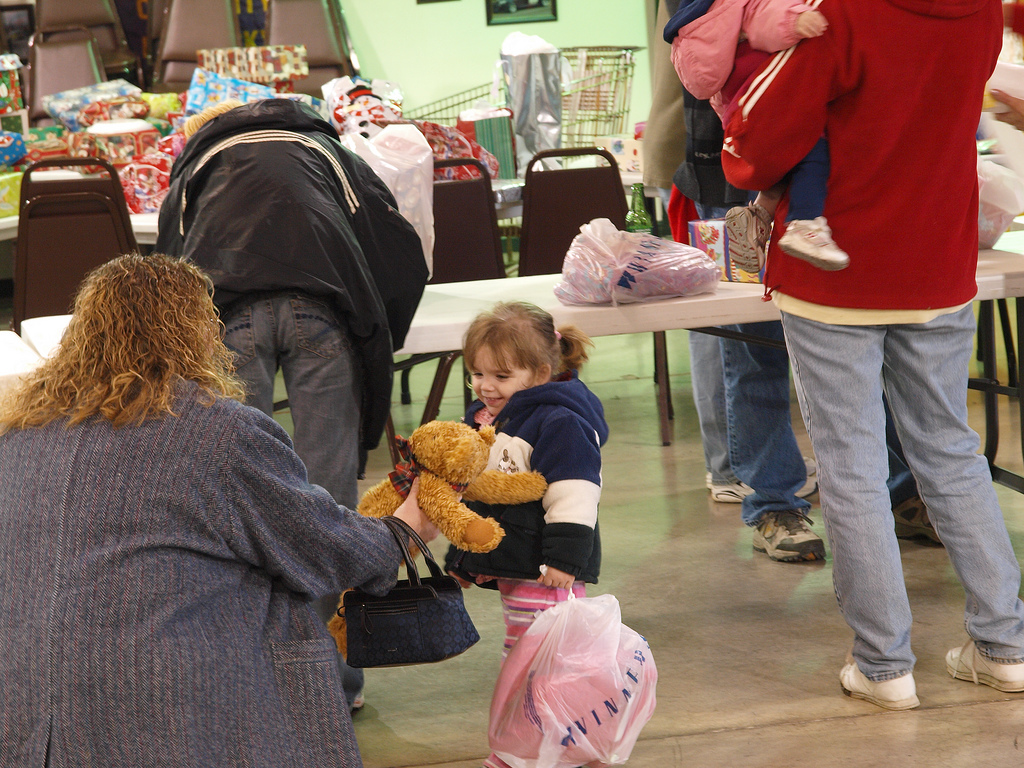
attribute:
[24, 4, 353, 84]
chairs — brown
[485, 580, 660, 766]
bag — pink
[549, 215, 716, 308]
bag — plastic